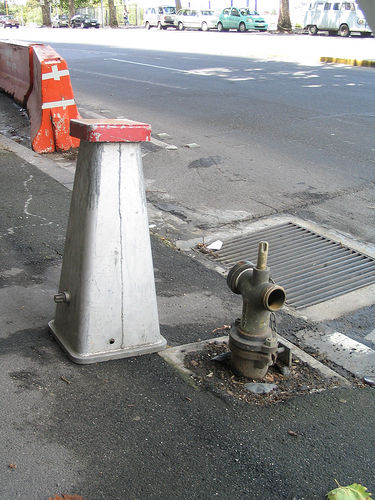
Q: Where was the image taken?
A: It was taken at the road.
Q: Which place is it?
A: It is a road.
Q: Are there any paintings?
A: No, there are no paintings.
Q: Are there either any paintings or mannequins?
A: No, there are no paintings or mannequins.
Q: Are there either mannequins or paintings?
A: No, there are no paintings or mannequins.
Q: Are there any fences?
A: No, there are no fences.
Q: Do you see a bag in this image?
A: No, there are no bags.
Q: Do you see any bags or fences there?
A: No, there are no bags or fences.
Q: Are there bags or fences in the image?
A: No, there are no bags or fences.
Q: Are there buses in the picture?
A: Yes, there is a bus.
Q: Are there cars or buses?
A: Yes, there is a bus.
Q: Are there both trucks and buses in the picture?
A: No, there is a bus but no trucks.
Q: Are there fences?
A: No, there are no fences.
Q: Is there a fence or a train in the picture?
A: No, there are no fences or trains.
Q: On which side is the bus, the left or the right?
A: The bus is on the right of the image.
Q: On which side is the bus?
A: The bus is on the right of the image.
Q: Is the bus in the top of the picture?
A: Yes, the bus is in the top of the image.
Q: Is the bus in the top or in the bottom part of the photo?
A: The bus is in the top of the image.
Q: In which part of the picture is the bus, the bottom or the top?
A: The bus is in the top of the image.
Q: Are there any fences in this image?
A: No, there are no fences.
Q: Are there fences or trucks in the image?
A: No, there are no fences or trucks.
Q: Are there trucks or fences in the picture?
A: No, there are no fences or trucks.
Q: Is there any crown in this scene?
A: No, there are no crowns.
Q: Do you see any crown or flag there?
A: No, there are no crowns or flags.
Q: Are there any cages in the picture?
A: No, there are no cages.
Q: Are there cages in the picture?
A: No, there are no cages.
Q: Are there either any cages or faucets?
A: No, there are no cages or faucets.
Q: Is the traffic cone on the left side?
A: Yes, the traffic cone is on the left of the image.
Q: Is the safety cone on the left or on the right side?
A: The safety cone is on the left of the image.